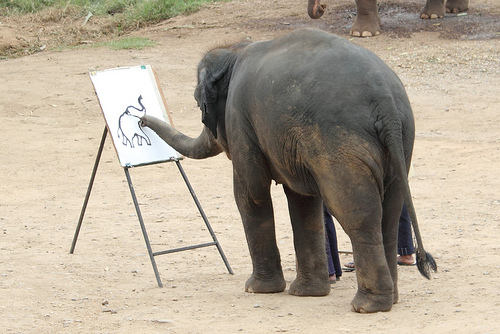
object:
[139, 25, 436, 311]
elephant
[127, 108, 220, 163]
trunk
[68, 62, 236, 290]
easel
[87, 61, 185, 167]
paper pad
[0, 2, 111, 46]
dried hay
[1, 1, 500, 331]
ground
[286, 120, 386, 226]
dirt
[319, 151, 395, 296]
leg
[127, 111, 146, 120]
paintbrush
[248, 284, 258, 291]
toe nails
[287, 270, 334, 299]
elephant foot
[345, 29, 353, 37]
toe nail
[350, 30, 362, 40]
toe nail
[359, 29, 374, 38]
toe nail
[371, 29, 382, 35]
toe nail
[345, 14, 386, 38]
elephant foot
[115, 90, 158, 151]
drawing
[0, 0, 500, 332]
dirt